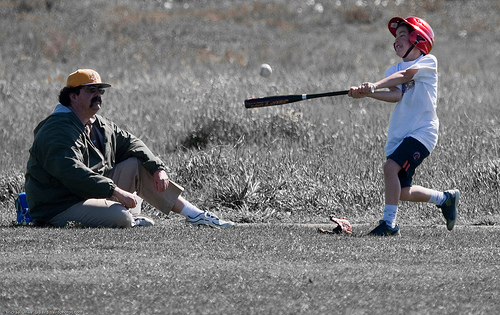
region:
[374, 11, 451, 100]
A boy wearing a batting helmet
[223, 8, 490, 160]
A boy swinging a bat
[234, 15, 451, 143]
A boy hitting a baseball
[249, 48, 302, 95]
A baseball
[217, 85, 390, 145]
A baseball bat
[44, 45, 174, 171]
A man in a yellow hat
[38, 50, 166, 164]
A man wearing sunglasses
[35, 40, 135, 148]
A man with a mustache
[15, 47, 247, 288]
A man sitting on the ground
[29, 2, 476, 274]
A man watching a boy hit a baseball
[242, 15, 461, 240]
a boy hitting a baseball with a bat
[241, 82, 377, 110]
black baseball bat with red letters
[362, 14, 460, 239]
a boy wearing a white shirt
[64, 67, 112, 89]
yellow baseball cap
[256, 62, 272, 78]
white baseball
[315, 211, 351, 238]
a brown baseball glove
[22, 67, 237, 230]
a man wearing a green jacket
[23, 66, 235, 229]
a man wearing a yellow baseball cap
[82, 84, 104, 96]
sunglasses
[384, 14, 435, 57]
a red helmet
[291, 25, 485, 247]
A boy with a white shirt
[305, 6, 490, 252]
A boy with black shorts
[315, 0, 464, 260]
The boy is wearing a red helmet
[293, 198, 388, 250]
A baseball mitt lies on the grass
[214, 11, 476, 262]
The boy swings the bat at the ball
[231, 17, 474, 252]
The boy is holding a black bat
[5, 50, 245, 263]
A man in a dark grey sweater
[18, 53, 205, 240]
The man has a yellow and blue hat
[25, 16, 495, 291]
The two people are on a grass field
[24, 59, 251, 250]
The man is sitting down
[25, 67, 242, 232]
older man sitting on the grass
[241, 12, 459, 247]
young boy playing baseball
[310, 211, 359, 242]
brown baseball glove on the grass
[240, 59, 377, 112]
black bat hitting white ball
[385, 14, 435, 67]
red baseball helmet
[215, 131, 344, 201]
gray grassy landscape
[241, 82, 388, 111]
two hands gripping a black bat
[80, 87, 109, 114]
big black mustache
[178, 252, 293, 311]
short gray grass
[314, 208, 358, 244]
A baseball glove on the ground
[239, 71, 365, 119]
A metal bat in a boy's hands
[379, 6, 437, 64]
A red baseball helmet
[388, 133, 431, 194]
Black shorts with two red stripes on a boy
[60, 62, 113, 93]
A yellow cap on a man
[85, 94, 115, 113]
A large mustache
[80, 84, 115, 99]
Sunglasses on a man's face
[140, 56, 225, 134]
Tall grass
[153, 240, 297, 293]
Short trimmed grass